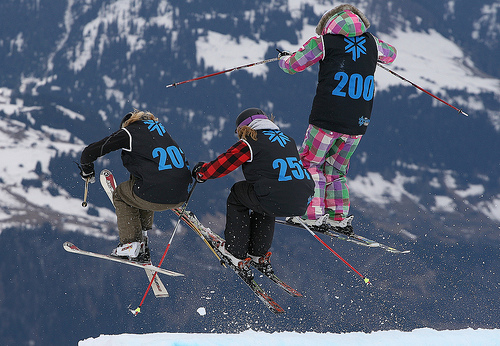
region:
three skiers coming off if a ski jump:
[52, 5, 469, 320]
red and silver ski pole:
[160, 44, 280, 89]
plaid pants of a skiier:
[298, 122, 355, 212]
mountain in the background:
[5, 5, 273, 96]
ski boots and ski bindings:
[207, 234, 278, 290]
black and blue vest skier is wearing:
[239, 126, 314, 218]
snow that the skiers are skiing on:
[77, 325, 497, 345]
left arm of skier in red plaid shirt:
[189, 138, 251, 183]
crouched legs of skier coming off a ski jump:
[222, 181, 315, 262]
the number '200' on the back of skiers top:
[331, 70, 379, 101]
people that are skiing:
[98, 29, 499, 294]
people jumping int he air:
[87, 33, 429, 328]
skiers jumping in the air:
[129, 121, 404, 329]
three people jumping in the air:
[69, 23, 474, 344]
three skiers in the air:
[87, 29, 493, 322]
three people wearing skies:
[77, 33, 446, 300]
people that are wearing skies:
[65, 70, 420, 328]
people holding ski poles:
[62, 43, 439, 295]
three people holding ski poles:
[127, 20, 403, 278]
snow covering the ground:
[16, 3, 211, 185]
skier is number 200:
[276, 5, 400, 240]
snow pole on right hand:
[370, 48, 475, 128]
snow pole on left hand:
[154, 50, 288, 94]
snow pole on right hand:
[294, 209, 381, 293]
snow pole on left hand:
[128, 162, 208, 317]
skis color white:
[60, 160, 180, 301]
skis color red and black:
[170, 205, 305, 321]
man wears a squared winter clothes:
[280, 0, 404, 239]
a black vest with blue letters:
[239, 123, 322, 198]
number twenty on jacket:
[148, 146, 183, 174]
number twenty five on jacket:
[273, 155, 303, 185]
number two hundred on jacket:
[331, 68, 374, 104]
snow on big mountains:
[201, 34, 256, 71]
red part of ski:
[312, 231, 357, 278]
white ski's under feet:
[57, 236, 182, 300]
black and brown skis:
[192, 216, 292, 318]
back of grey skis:
[343, 226, 408, 269]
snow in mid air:
[311, 288, 376, 325]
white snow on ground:
[288, 329, 334, 344]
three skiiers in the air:
[53, 1, 454, 313]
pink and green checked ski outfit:
[276, 6, 406, 239]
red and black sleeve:
[185, 129, 254, 186]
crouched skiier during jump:
[55, 92, 195, 319]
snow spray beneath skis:
[199, 226, 479, 344]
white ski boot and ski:
[60, 235, 185, 290]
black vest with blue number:
[317, 33, 379, 134]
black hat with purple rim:
[232, 101, 272, 133]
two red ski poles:
[152, 31, 484, 115]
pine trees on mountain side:
[5, 2, 274, 100]